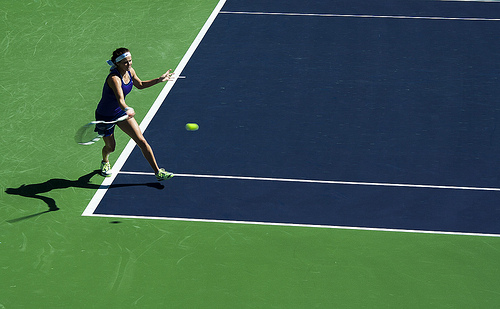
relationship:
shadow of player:
[9, 172, 165, 208] [93, 45, 173, 179]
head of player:
[111, 50, 135, 70] [93, 45, 173, 179]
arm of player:
[129, 70, 179, 88] [93, 45, 173, 179]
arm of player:
[110, 78, 134, 120] [93, 45, 173, 179]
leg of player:
[114, 114, 169, 178] [93, 45, 173, 179]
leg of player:
[101, 125, 118, 174] [93, 45, 173, 179]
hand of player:
[124, 107, 138, 118] [93, 45, 173, 179]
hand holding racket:
[124, 107, 138, 118] [72, 115, 134, 147]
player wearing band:
[93, 45, 173, 179] [109, 52, 134, 62]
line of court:
[215, 3, 498, 30] [3, 3, 499, 308]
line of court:
[114, 162, 499, 201] [3, 3, 499, 308]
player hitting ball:
[93, 45, 173, 179] [184, 121, 201, 131]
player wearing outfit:
[93, 45, 173, 179] [96, 75, 137, 134]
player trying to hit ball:
[93, 45, 173, 179] [184, 121, 201, 131]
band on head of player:
[109, 52, 134, 62] [93, 45, 173, 179]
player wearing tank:
[93, 45, 173, 179] [103, 72, 139, 107]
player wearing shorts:
[93, 45, 173, 179] [95, 113, 130, 133]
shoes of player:
[98, 159, 174, 182] [93, 45, 173, 179]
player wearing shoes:
[93, 45, 173, 179] [98, 159, 174, 182]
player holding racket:
[93, 45, 173, 179] [72, 115, 134, 147]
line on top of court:
[215, 3, 498, 30] [3, 3, 499, 308]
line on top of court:
[114, 162, 499, 201] [3, 3, 499, 308]